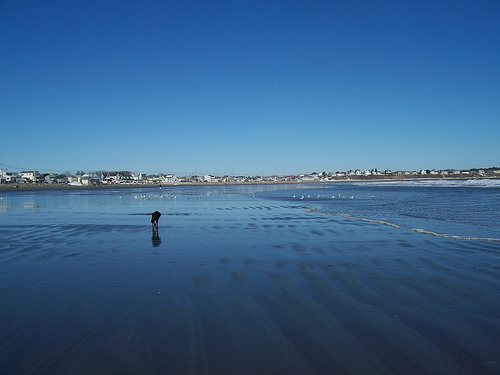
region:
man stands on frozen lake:
[141, 200, 171, 232]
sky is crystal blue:
[5, 11, 184, 131]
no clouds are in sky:
[25, 16, 184, 121]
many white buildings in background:
[20, 159, 187, 190]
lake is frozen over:
[39, 204, 139, 362]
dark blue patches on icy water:
[62, 180, 334, 260]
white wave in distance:
[359, 178, 495, 199]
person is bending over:
[148, 204, 164, 237]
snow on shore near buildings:
[261, 170, 360, 190]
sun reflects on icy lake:
[47, 178, 256, 199]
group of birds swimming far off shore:
[292, 194, 374, 199]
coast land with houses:
[0, 168, 499, 188]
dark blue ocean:
[1, 180, 499, 374]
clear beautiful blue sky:
[0, 0, 497, 176]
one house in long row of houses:
[17, 170, 37, 180]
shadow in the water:
[150, 235, 161, 245]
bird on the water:
[292, 192, 294, 195]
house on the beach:
[420, 168, 425, 173]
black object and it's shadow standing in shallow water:
[150, 210, 160, 246]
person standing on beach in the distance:
[16, 184, 18, 189]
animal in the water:
[143, 206, 171, 238]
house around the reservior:
[83, 179, 92, 186]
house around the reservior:
[121, 175, 133, 183]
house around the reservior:
[143, 174, 155, 180]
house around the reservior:
[198, 173, 210, 185]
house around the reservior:
[206, 173, 218, 183]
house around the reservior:
[254, 173, 264, 181]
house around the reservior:
[321, 168, 328, 181]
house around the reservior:
[352, 168, 362, 179]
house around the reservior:
[421, 166, 426, 178]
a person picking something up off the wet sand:
[137, 203, 200, 253]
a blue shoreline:
[191, 175, 479, 356]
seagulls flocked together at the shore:
[98, 184, 375, 210]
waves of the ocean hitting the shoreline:
[292, 177, 492, 252]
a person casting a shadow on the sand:
[147, 198, 170, 253]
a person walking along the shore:
[141, 198, 185, 268]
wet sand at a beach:
[199, 225, 498, 371]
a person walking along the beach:
[134, 207, 286, 327]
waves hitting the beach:
[381, 178, 492, 240]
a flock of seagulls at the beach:
[277, 183, 387, 211]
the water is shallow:
[193, 178, 394, 255]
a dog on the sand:
[124, 175, 206, 265]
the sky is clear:
[71, 93, 328, 165]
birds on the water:
[271, 165, 455, 230]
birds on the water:
[284, 185, 404, 229]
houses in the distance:
[26, 156, 199, 191]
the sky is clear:
[95, 38, 296, 135]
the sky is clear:
[306, 45, 396, 167]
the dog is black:
[148, 205, 192, 244]